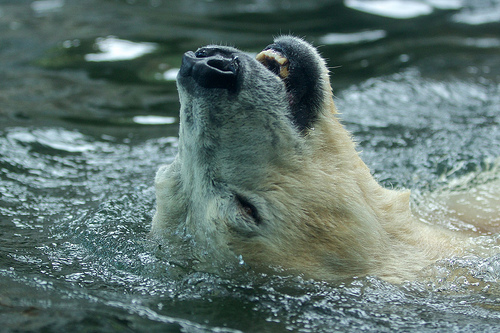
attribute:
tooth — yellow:
[259, 45, 273, 58]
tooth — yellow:
[261, 49, 283, 70]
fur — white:
[155, 146, 498, 300]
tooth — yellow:
[264, 47, 275, 55]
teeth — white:
[251, 43, 289, 67]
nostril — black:
[163, 20, 265, 106]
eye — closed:
[228, 190, 262, 229]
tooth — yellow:
[270, 52, 287, 70]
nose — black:
[180, 43, 240, 94]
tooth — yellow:
[257, 51, 275, 61]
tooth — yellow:
[255, 50, 265, 58]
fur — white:
[313, 180, 360, 252]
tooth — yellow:
[277, 63, 288, 78]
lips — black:
[260, 32, 322, 134]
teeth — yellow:
[251, 43, 292, 75]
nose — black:
[173, 41, 211, 90]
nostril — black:
[180, 48, 233, 82]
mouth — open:
[224, 32, 327, 128]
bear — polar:
[148, 31, 498, 291]